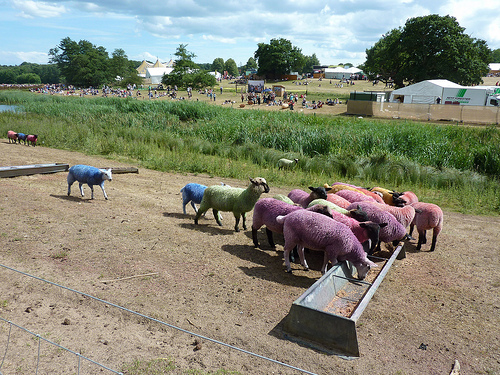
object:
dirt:
[119, 211, 158, 232]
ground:
[0, 132, 500, 326]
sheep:
[67, 165, 113, 200]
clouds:
[151, 3, 241, 36]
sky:
[0, 4, 500, 66]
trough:
[287, 242, 405, 317]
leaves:
[75, 60, 107, 81]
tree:
[362, 13, 492, 88]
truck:
[313, 69, 325, 78]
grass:
[0, 87, 500, 216]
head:
[104, 171, 113, 182]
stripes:
[210, 196, 228, 203]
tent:
[146, 68, 200, 86]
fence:
[371, 101, 498, 125]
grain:
[323, 289, 357, 312]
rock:
[76, 253, 97, 275]